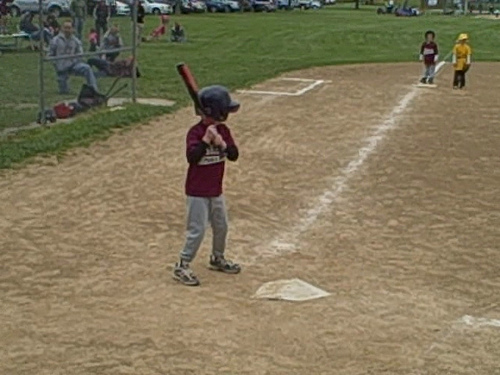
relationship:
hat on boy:
[456, 31, 466, 38] [449, 30, 474, 89]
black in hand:
[192, 82, 242, 122] [202, 122, 217, 144]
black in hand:
[192, 82, 242, 122] [210, 128, 227, 148]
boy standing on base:
[400, 16, 445, 88] [410, 76, 442, 93]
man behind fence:
[35, 22, 100, 97] [0, 2, 139, 132]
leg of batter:
[174, 190, 209, 265] [160, 58, 251, 284]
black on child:
[192, 82, 242, 122] [181, 79, 243, 281]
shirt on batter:
[181, 112, 239, 199] [160, 58, 251, 284]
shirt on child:
[181, 112, 239, 199] [166, 38, 286, 303]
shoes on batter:
[168, 257, 244, 288] [160, 58, 251, 284]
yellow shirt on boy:
[452, 43, 471, 70] [449, 30, 474, 89]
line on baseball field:
[251, 50, 452, 270] [1, 56, 498, 373]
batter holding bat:
[160, 58, 251, 284] [167, 58, 229, 152]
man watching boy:
[35, 22, 100, 97] [166, 59, 265, 290]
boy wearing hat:
[449, 30, 474, 89] [456, 31, 466, 38]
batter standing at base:
[160, 58, 251, 284] [240, 264, 342, 316]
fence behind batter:
[0, 2, 139, 132] [170, 83, 242, 288]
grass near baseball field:
[2, 13, 498, 69] [1, 56, 498, 373]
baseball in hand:
[175, 59, 224, 157] [206, 123, 217, 138]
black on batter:
[192, 82, 242, 122] [160, 58, 251, 284]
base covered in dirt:
[240, 264, 342, 316] [397, 193, 477, 267]